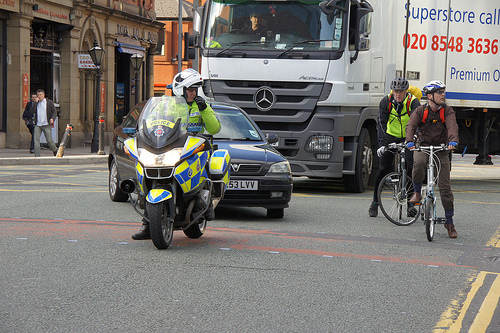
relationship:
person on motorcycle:
[126, 71, 230, 251] [120, 98, 231, 248]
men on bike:
[404, 82, 464, 245] [414, 144, 461, 241]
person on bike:
[367, 79, 425, 233] [378, 141, 422, 232]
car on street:
[111, 97, 293, 222] [2, 160, 496, 331]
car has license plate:
[111, 97, 293, 222] [221, 180, 261, 190]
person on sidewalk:
[32, 90, 59, 158] [3, 144, 121, 166]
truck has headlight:
[176, 1, 496, 190] [306, 130, 333, 161]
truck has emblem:
[176, 1, 496, 190] [252, 86, 277, 114]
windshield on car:
[212, 109, 266, 145] [111, 97, 293, 222]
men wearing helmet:
[404, 82, 464, 245] [424, 80, 449, 90]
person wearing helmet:
[367, 79, 425, 233] [392, 77, 409, 89]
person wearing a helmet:
[126, 71, 230, 251] [170, 69, 204, 95]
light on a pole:
[89, 37, 105, 67] [89, 41, 110, 153]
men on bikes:
[369, 77, 464, 245] [374, 141, 457, 243]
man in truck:
[237, 8, 273, 45] [176, 1, 496, 190]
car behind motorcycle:
[111, 97, 293, 222] [120, 98, 231, 248]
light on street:
[89, 37, 105, 67] [2, 160, 496, 331]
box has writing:
[391, 0, 499, 120] [403, 4, 498, 86]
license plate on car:
[221, 180, 261, 190] [111, 97, 293, 222]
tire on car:
[108, 156, 127, 201] [111, 97, 293, 222]